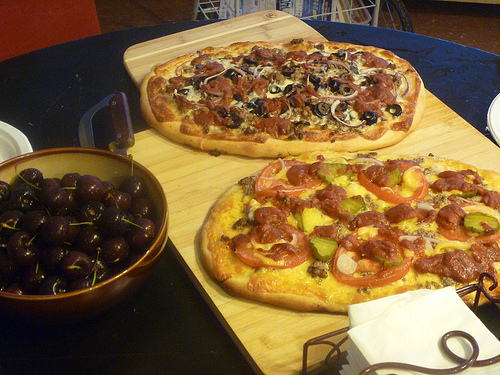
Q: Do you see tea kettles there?
A: No, there are no tea kettles.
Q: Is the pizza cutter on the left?
A: Yes, the pizza cutter is on the left of the image.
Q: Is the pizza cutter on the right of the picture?
A: No, the pizza cutter is on the left of the image.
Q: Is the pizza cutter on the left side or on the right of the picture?
A: The pizza cutter is on the left of the image.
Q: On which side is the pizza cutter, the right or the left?
A: The pizza cutter is on the left of the image.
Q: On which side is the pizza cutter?
A: The pizza cutter is on the left of the image.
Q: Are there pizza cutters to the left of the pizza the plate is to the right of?
A: Yes, there is a pizza cutter to the left of the pizza.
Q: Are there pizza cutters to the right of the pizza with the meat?
A: No, the pizza cutter is to the left of the pizza.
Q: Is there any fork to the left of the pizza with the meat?
A: No, there is a pizza cutter to the left of the pizza.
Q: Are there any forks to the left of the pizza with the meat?
A: No, there is a pizza cutter to the left of the pizza.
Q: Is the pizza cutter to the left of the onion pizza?
A: Yes, the pizza cutter is to the left of the pizza.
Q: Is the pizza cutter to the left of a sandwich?
A: No, the pizza cutter is to the left of the pizza.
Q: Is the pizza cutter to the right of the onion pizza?
A: No, the pizza cutter is to the left of the pizza.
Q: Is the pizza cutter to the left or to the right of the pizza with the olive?
A: The pizza cutter is to the left of the pizza.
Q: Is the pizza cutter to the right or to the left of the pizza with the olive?
A: The pizza cutter is to the left of the pizza.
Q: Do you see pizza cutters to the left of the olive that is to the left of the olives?
A: Yes, there is a pizza cutter to the left of the olive.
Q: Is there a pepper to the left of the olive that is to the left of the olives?
A: No, there is a pizza cutter to the left of the olive.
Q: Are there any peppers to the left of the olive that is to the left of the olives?
A: No, there is a pizza cutter to the left of the olive.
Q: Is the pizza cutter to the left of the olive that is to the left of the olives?
A: Yes, the pizza cutter is to the left of the olive.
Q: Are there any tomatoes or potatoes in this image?
A: Yes, there is a tomato.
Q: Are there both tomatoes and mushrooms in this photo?
A: No, there is a tomato but no mushrooms.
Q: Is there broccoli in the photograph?
A: No, there is no broccoli.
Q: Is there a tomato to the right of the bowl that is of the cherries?
A: Yes, there is a tomato to the right of the bowl.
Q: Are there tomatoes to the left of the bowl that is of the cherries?
A: No, the tomato is to the right of the bowl.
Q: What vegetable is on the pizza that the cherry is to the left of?
A: The vegetable is a tomato.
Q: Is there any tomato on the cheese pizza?
A: Yes, there is a tomato on the pizza.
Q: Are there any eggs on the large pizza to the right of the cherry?
A: No, there is a tomato on the pizza.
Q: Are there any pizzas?
A: Yes, there is a pizza.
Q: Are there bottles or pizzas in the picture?
A: Yes, there is a pizza.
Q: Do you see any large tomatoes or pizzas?
A: Yes, there is a large pizza.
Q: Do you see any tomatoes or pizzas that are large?
A: Yes, the pizza is large.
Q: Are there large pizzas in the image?
A: Yes, there is a large pizza.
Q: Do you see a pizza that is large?
A: Yes, there is a pizza that is large.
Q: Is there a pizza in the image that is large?
A: Yes, there is a pizza that is large.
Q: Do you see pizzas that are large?
A: Yes, there is a pizza that is large.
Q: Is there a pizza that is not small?
A: Yes, there is a large pizza.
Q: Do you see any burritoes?
A: No, there are no burritoes.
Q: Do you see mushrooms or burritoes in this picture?
A: No, there are no burritoes or mushrooms.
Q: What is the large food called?
A: The food is a pizza.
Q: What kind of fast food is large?
A: The fast food is a pizza.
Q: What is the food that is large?
A: The food is a pizza.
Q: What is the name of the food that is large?
A: The food is a pizza.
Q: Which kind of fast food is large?
A: The fast food is a pizza.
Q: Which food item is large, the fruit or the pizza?
A: The pizza is large.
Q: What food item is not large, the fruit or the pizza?
A: The fruit is not large.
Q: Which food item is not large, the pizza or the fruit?
A: The fruit is not large.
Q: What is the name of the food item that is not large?
A: The food item is a fruit.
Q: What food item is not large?
A: The food item is a fruit.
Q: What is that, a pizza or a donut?
A: That is a pizza.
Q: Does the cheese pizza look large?
A: Yes, the pizza is large.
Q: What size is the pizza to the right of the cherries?
A: The pizza is large.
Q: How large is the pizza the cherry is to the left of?
A: The pizza is large.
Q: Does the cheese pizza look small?
A: No, the pizza is large.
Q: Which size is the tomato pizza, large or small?
A: The pizza is large.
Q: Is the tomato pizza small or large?
A: The pizza is large.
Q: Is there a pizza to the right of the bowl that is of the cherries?
A: Yes, there is a pizza to the right of the bowl.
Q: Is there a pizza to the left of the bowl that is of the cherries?
A: No, the pizza is to the right of the bowl.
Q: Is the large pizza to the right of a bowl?
A: Yes, the pizza is to the right of a bowl.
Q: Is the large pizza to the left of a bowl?
A: No, the pizza is to the right of a bowl.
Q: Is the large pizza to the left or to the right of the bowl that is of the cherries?
A: The pizza is to the right of the bowl.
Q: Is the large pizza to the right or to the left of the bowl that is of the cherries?
A: The pizza is to the right of the bowl.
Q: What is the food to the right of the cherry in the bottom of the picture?
A: The food is a pizza.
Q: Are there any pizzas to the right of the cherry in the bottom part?
A: Yes, there is a pizza to the right of the cherry.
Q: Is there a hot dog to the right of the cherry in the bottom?
A: No, there is a pizza to the right of the cherry.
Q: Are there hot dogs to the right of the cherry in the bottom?
A: No, there is a pizza to the right of the cherry.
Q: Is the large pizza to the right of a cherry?
A: Yes, the pizza is to the right of a cherry.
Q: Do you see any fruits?
A: Yes, there is a fruit.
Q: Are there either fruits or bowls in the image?
A: Yes, there is a fruit.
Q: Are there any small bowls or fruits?
A: Yes, there is a small fruit.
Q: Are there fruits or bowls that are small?
A: Yes, the fruit is small.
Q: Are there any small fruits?
A: Yes, there is a small fruit.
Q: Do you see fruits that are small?
A: Yes, there is a small fruit.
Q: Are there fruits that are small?
A: Yes, there is a fruit that is small.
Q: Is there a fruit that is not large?
A: Yes, there is a small fruit.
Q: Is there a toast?
A: No, there are no toasts.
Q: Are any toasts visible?
A: No, there are no toasts.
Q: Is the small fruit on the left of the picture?
A: Yes, the fruit is on the left of the image.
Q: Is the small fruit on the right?
A: No, the fruit is on the left of the image.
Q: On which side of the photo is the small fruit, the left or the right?
A: The fruit is on the left of the image.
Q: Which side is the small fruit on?
A: The fruit is on the left of the image.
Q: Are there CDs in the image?
A: No, there are no cds.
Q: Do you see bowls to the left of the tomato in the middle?
A: Yes, there is a bowl to the left of the tomato.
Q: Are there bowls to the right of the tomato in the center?
A: No, the bowl is to the left of the tomato.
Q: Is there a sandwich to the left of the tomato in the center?
A: No, there is a bowl to the left of the tomato.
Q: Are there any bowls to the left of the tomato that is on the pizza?
A: Yes, there is a bowl to the left of the tomato.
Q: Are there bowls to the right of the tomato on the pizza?
A: No, the bowl is to the left of the tomato.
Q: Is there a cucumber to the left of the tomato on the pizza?
A: No, there is a bowl to the left of the tomato.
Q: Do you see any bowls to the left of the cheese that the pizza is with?
A: Yes, there is a bowl to the left of the cheese.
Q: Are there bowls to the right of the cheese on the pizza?
A: No, the bowl is to the left of the cheese.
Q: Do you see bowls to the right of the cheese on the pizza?
A: No, the bowl is to the left of the cheese.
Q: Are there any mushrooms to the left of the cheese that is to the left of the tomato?
A: No, there is a bowl to the left of the cheese.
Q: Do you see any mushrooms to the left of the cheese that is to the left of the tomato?
A: No, there is a bowl to the left of the cheese.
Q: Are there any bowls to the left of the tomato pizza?
A: Yes, there is a bowl to the left of the pizza.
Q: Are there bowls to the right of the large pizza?
A: No, the bowl is to the left of the pizza.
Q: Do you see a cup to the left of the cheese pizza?
A: No, there is a bowl to the left of the pizza.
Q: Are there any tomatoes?
A: Yes, there is a tomato.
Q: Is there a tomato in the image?
A: Yes, there is a tomato.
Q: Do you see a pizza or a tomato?
A: Yes, there is a tomato.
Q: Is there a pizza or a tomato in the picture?
A: Yes, there is a tomato.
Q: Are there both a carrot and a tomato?
A: No, there is a tomato but no carrots.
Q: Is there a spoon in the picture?
A: No, there are no spoons.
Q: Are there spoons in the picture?
A: No, there are no spoons.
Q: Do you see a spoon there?
A: No, there are no spoons.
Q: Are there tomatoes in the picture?
A: Yes, there is a tomato.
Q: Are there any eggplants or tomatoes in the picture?
A: Yes, there is a tomato.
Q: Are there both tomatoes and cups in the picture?
A: No, there is a tomato but no cups.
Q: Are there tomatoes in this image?
A: Yes, there is a tomato.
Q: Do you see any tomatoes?
A: Yes, there is a tomato.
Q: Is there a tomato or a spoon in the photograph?
A: Yes, there is a tomato.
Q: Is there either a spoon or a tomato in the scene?
A: Yes, there is a tomato.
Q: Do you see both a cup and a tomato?
A: No, there is a tomato but no cups.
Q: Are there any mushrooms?
A: No, there are no mushrooms.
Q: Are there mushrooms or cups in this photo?
A: No, there are no mushrooms or cups.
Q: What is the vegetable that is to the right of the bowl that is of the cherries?
A: The vegetable is a tomato.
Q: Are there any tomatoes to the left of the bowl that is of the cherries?
A: No, the tomato is to the right of the bowl.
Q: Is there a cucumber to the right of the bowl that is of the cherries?
A: No, there is a tomato to the right of the bowl.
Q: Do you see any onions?
A: Yes, there is an onion.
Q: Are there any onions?
A: Yes, there is an onion.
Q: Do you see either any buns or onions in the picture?
A: Yes, there is an onion.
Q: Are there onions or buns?
A: Yes, there is an onion.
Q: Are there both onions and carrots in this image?
A: No, there is an onion but no carrots.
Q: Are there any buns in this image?
A: No, there are no buns.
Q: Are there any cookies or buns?
A: No, there are no buns or cookies.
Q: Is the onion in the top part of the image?
A: Yes, the onion is in the top of the image.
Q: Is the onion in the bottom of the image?
A: No, the onion is in the top of the image.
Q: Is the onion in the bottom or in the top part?
A: The onion is in the top of the image.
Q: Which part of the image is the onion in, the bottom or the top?
A: The onion is in the top of the image.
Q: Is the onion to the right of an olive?
A: Yes, the onion is to the right of an olive.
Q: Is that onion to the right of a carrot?
A: No, the onion is to the right of an olive.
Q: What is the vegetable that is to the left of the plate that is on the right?
A: The vegetable is an onion.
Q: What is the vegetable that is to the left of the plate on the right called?
A: The vegetable is an onion.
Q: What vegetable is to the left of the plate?
A: The vegetable is an onion.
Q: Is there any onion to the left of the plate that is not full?
A: Yes, there is an onion to the left of the plate.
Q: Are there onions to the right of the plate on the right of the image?
A: No, the onion is to the left of the plate.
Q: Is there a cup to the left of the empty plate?
A: No, there is an onion to the left of the plate.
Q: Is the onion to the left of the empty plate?
A: Yes, the onion is to the left of the plate.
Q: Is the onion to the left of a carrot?
A: No, the onion is to the left of the plate.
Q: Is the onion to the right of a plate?
A: No, the onion is to the left of a plate.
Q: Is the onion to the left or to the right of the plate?
A: The onion is to the left of the plate.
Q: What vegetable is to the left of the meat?
A: The vegetable is an onion.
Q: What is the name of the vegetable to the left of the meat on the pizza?
A: The vegetable is an onion.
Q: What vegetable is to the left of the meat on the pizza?
A: The vegetable is an onion.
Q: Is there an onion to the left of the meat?
A: Yes, there is an onion to the left of the meat.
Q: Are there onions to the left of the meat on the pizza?
A: Yes, there is an onion to the left of the meat.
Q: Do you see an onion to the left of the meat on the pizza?
A: Yes, there is an onion to the left of the meat.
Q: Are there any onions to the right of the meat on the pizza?
A: No, the onion is to the left of the meat.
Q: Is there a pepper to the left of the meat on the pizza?
A: No, there is an onion to the left of the meat.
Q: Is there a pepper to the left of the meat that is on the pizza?
A: No, there is an onion to the left of the meat.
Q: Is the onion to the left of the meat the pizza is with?
A: Yes, the onion is to the left of the meat.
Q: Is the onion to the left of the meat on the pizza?
A: Yes, the onion is to the left of the meat.